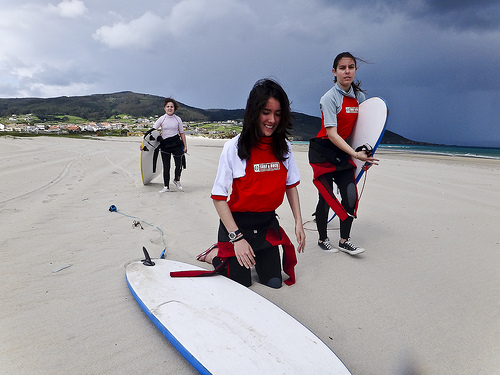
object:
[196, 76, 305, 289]
girl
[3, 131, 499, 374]
sand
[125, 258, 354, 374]
surfboard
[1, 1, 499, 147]
sky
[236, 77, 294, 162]
hair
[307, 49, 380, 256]
girl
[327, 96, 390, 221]
surfboard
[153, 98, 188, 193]
woman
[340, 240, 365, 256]
shoes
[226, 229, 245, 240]
watch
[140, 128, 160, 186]
surfboard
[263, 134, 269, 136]
mole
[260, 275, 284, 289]
knees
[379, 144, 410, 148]
waves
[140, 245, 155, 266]
fin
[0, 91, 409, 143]
mountains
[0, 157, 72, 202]
marks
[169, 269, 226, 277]
strap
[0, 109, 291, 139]
town